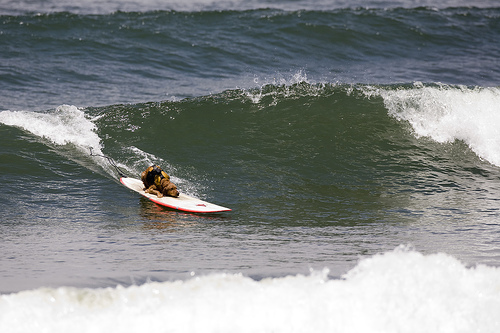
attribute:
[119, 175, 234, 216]
surfboard — white, red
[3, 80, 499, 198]
wave — frothy, white, large, green, breaking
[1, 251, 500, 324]
splash — white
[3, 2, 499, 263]
water — wavy, blue, murky, engaging, ripply, zealous, foamy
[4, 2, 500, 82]
wave — small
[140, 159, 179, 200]
dog — brown, lying down, surfing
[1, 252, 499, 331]
wave — frothy, white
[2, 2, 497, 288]
ocean — rough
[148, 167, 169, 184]
vest — yellow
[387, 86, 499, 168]
seafoam — white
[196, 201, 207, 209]
logo — red